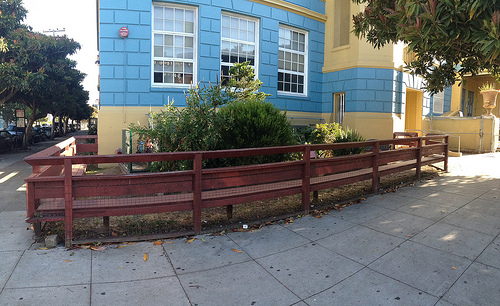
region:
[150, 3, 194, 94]
the large window of the house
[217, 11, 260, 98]
the large window of the house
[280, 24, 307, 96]
the large window of the house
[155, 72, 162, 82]
the window pane of the window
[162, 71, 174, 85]
the window pane of the window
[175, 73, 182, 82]
the window pane of the window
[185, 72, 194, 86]
the window pane of the window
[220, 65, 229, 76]
the window pane of the window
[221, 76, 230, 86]
the window pane of the window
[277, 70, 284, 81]
the window pane of the window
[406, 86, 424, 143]
the door way of the house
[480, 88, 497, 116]
the large plant pot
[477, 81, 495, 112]
the large potted plant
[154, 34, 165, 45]
the small window pane of the window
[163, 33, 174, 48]
the small window pane of the window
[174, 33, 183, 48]
the small window pane of the window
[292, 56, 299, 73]
the small window pane of the window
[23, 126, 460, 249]
wooden and wire fence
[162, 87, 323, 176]
bushes beside building inside fence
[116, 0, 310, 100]
windows on the side of building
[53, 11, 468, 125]
blue stripe horizontally on building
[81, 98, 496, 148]
tan color paint at buildings bottom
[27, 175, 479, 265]
leaves along walk way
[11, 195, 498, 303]
concrete walk way along building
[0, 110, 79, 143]
cars parked along street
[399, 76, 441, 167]
doorway into building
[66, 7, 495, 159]
painted brick building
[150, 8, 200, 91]
A white framed window.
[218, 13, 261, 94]
A middle white framed window.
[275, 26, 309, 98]
A third white framed window.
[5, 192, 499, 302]
Big quadrant stone side walk.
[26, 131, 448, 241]
Part of the brown front facing fence.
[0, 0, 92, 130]
Green hanging leafy trees.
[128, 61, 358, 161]
Green foliage in front of the house.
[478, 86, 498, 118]
A white stone pot design.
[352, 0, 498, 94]
Over hanging leafy tree to the right side.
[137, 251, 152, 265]
A small orange leaf on the side walk.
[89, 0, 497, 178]
pale yellow and light blue painted brick house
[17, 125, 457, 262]
rusty brown painted wooden fence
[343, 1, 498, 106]
low hanging branches of a leafy green tree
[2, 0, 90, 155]
row of medium height leafy green trees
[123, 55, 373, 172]
bushy green shrubbery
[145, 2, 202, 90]
tall window with twenty four panes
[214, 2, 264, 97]
tall window with twenty four panes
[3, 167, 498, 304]
large grey square concrete side walk tiles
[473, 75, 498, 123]
large urn for plants